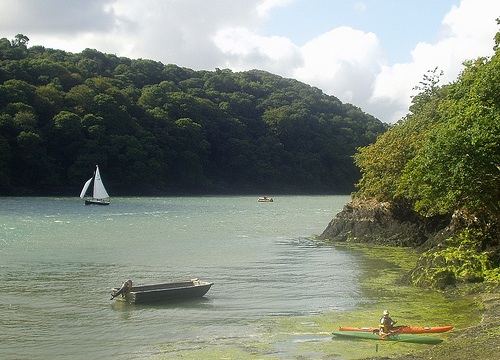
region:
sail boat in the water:
[75, 158, 116, 208]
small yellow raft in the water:
[252, 192, 274, 205]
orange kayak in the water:
[329, 305, 454, 344]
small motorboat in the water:
[106, 268, 213, 310]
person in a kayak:
[329, 297, 465, 348]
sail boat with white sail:
[76, 155, 111, 210]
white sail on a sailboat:
[90, 161, 114, 201]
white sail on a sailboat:
[75, 173, 95, 200]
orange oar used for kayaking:
[367, 325, 403, 344]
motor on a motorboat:
[106, 275, 135, 302]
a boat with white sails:
[75, 165, 112, 202]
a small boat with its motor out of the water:
[101, 276, 211, 301]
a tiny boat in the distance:
[255, 192, 270, 199]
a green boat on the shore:
[330, 330, 441, 340]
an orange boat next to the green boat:
[337, 307, 452, 327]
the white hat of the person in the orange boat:
[381, 307, 386, 312]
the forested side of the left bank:
[0, 37, 382, 192]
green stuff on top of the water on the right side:
[195, 242, 460, 354]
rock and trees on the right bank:
[320, 22, 495, 272]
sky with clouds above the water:
[0, 0, 497, 122]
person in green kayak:
[325, 321, 443, 352]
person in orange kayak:
[337, 322, 454, 334]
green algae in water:
[355, 242, 476, 353]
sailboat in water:
[72, 148, 122, 223]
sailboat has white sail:
[65, 160, 125, 215]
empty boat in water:
[106, 260, 220, 317]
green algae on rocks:
[395, 211, 493, 308]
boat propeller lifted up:
[93, 252, 221, 317]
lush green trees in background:
[2, 41, 363, 205]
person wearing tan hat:
[380, 307, 393, 322]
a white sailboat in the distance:
[77, 164, 109, 203]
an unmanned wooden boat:
[105, 274, 217, 306]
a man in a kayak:
[333, 310, 455, 345]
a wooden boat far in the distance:
[254, 194, 276, 204]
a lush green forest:
[0, 35, 385, 197]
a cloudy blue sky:
[0, 0, 447, 69]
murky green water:
[359, 242, 474, 317]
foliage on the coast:
[429, 232, 497, 358]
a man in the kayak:
[376, 305, 393, 339]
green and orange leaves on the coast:
[374, 80, 499, 265]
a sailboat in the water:
[40, 123, 232, 246]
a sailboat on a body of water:
[32, 137, 281, 330]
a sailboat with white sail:
[41, 128, 196, 242]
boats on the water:
[22, 115, 332, 357]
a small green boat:
[109, 255, 329, 352]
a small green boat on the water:
[58, 229, 306, 358]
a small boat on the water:
[79, 236, 247, 359]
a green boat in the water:
[77, 239, 229, 351]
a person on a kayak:
[322, 262, 465, 354]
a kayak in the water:
[310, 293, 445, 358]